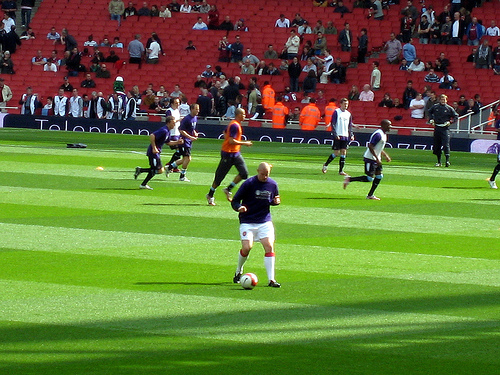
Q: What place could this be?
A: It is a field.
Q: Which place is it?
A: It is a field.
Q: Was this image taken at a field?
A: Yes, it was taken in a field.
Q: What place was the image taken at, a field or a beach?
A: It was taken at a field.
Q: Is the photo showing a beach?
A: No, the picture is showing a field.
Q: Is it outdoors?
A: Yes, it is outdoors.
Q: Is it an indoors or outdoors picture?
A: It is outdoors.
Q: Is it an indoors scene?
A: No, it is outdoors.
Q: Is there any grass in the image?
A: Yes, there is grass.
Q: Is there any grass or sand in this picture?
A: Yes, there is grass.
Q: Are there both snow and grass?
A: No, there is grass but no snow.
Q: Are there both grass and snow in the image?
A: No, there is grass but no snow.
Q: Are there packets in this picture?
A: No, there are no packets.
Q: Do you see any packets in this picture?
A: No, there are no packets.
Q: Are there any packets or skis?
A: No, there are no packets or skis.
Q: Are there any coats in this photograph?
A: Yes, there is a coat.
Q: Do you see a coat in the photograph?
A: Yes, there is a coat.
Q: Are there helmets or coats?
A: Yes, there is a coat.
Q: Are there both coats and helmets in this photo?
A: No, there is a coat but no helmets.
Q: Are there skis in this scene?
A: No, there are no skis.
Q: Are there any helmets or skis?
A: No, there are no skis or helmets.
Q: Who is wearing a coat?
A: The man is wearing a coat.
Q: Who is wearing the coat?
A: The man is wearing a coat.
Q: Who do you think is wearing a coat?
A: The man is wearing a coat.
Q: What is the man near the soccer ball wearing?
A: The man is wearing a coat.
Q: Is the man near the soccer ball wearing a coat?
A: Yes, the man is wearing a coat.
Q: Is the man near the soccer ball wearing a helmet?
A: No, the man is wearing a coat.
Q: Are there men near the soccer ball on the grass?
A: Yes, there is a man near the soccer ball.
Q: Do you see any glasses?
A: No, there are no glasses.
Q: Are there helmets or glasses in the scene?
A: No, there are no glasses or helmets.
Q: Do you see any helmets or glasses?
A: No, there are no glasses or helmets.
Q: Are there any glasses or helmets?
A: No, there are no glasses or helmets.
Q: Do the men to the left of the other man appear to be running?
A: Yes, the men are running.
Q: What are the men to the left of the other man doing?
A: The men are running.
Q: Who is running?
A: The men are running.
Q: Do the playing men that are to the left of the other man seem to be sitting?
A: No, the men are running.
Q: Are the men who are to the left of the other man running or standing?
A: The men are running.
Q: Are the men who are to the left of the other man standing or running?
A: The men are running.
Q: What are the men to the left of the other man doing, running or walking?
A: The men are running.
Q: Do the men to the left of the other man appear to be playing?
A: Yes, the men are playing.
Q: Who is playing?
A: The men are playing.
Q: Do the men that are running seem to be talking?
A: No, the men are playing.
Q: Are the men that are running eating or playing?
A: The men are playing.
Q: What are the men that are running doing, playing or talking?
A: The men are playing.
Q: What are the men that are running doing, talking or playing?
A: The men are playing.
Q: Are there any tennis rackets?
A: No, there are no tennis rackets.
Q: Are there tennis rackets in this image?
A: No, there are no tennis rackets.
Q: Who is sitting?
A: The people are sitting.